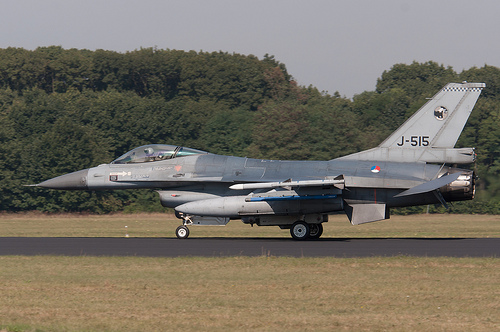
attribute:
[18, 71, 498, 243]
plane — gray, pointy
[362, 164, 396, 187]
circle — white, red, blue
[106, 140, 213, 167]
top — dome-shaped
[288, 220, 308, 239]
wheel — black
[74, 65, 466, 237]
plane — military, gray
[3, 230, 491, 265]
runway — concrete, gray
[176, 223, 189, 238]
wheel — black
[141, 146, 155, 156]
helmet — white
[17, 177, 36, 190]
front — needle shaped